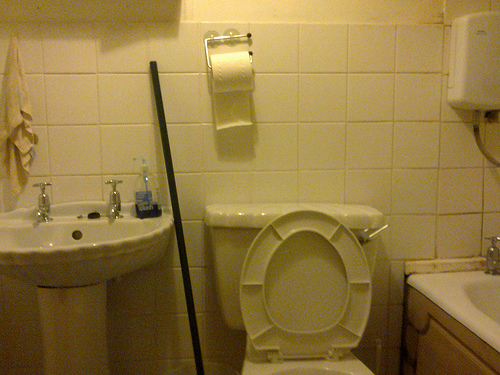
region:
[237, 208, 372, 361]
a toilet seat on the toilet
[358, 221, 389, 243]
a metal flush handle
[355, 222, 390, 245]
a flush handle on the toilet's tank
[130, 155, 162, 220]
hand soap in a plastic bottle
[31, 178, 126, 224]
two knobs on the sink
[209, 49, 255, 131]
a roll of tissue paper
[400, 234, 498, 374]
part of a bathtub beside the toilet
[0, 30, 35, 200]
a towel hanging on the wall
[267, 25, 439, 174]
ceramic wall tiles in the bathroom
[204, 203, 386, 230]
the top to the toilet's tank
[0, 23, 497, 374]
White tile on a bathroom wall.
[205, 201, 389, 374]
A white toilet with the seat cover up.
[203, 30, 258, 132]
A roll of toilet paper on a holder.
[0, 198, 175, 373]
A white pedestal sink.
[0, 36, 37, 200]
A white cloth hanging on a wall.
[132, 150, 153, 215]
Toothbrush in a toothbrush holder.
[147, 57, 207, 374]
A black stick leaning against the wall.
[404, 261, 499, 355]
A white bathtub.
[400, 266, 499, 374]
A wooden bathtub frame.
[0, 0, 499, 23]
White paint on the wall above the tile.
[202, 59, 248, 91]
toilet paper on roll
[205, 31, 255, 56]
roll on the wall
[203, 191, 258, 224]
tank of the toilet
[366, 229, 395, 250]
lever of the toilet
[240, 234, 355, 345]
lid of the toilet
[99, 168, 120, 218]
faucet on the sink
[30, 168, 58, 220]
faucet on the sink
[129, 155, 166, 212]
soap on the sink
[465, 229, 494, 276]
faucet of the tub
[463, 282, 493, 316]
bathtub on the right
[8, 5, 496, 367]
the bathroom has tiled walls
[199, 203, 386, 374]
a toilet is in the bathroom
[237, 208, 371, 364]
the seat of the toilet is up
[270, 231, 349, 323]
the lid of the toilet is up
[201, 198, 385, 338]
the water closet has a chrome handle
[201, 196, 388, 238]
a lid is on the water closet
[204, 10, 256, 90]
the the toilet paper holder is chrome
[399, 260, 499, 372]
a bathtub is in the room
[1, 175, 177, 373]
the pedestal sink is white porcelain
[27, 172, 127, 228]
the faucets on the sink are chrome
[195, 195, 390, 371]
a white toilet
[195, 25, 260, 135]
a tissue roll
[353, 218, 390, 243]
a flush handle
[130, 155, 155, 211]
a soap dispenser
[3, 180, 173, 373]
a white sink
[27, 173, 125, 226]
a faucets set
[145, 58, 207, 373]
handle on leaning against sink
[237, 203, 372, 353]
the lid is up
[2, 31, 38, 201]
a towel hanging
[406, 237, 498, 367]
a big white tub